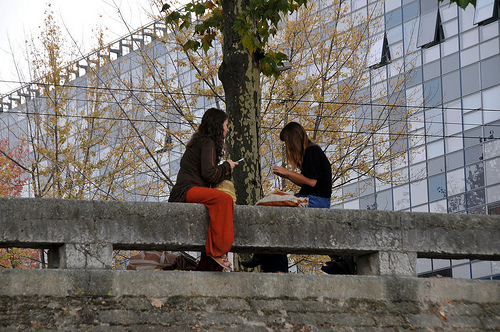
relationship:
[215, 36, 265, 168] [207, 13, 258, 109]
trunk of tree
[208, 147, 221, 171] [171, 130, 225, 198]
stripe on shirt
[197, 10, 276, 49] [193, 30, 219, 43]
leaves arfe green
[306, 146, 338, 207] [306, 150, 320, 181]
shirt has short sleeves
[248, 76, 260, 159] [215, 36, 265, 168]
moss on trunk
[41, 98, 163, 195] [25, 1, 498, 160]
windows on building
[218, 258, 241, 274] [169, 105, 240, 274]
foot of girl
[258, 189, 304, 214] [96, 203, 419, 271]
bag on wall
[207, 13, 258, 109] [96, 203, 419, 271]
tree by wall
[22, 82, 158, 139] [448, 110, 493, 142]
wires for electric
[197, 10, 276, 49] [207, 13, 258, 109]
leaves on tree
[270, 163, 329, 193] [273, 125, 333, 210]
arm of woman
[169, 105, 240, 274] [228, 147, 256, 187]
girl holding phone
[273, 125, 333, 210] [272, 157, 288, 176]
woman with phone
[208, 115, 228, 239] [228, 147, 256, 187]
girl using phone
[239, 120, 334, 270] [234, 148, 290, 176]
woman using phones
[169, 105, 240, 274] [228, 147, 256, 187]
girl with phone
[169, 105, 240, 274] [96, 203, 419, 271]
girl sitting on wall